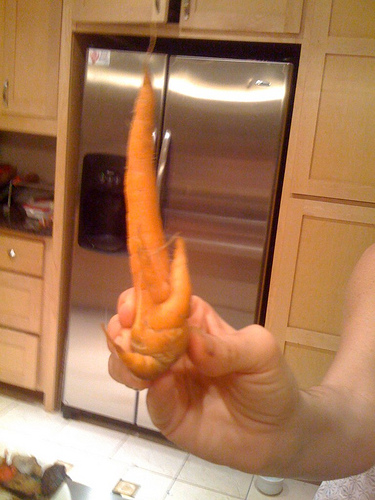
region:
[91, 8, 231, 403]
person holding carrot up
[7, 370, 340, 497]
white tile on floor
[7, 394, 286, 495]
dark grout on floor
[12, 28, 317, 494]
stainless steel fridge in back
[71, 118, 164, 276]
black water dispenser of fridge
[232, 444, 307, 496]
white dish on floor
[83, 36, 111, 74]
white tag on fridqe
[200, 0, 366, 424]
light brown side cabinets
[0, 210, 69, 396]
light brown kitchen drawer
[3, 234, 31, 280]
silver knob on draw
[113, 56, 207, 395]
An odd shaped carrot.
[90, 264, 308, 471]
Hand holding a carrot.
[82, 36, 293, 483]
Large stainless steel refrigerator.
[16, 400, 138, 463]
Tile floor in a kitchen.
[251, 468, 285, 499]
Bowl on the floor.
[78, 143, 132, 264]
Ice maker on a refrigerator.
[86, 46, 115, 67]
Magnet on the refrigerator.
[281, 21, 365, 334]
Several wooden cabinets in the kitchen.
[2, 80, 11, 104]
The handle of a wooden cabinet.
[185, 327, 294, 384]
A person's crooked thumb.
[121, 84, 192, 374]
a nasty looking orange carrot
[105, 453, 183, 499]
a tile kitchen floor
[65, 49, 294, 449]
a silver stainless steel fridge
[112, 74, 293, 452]
a woman holding an orange carrot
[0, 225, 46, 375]
a brown wooden cabinet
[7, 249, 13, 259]
a metal knob on a cabinet door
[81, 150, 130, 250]
a black water dispensor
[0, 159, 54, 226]
a granite kitchen countertop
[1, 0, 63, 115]
a wooden cabinet with metal handle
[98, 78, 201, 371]
a strange orange carrot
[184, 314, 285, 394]
a thumb of a hand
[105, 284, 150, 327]
the index finger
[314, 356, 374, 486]
the elbow is bend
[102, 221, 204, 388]
carrots has bifurcations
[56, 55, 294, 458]
a refrigerator on back a carrot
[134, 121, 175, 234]
handles of a refrigerator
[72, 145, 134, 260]
water dispenser of refrigerator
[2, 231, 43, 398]
cabinets below a counter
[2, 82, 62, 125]
cabinets on top a counter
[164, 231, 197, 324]
a small carrot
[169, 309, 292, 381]
the thumb of a person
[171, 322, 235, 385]
the fingernail of a person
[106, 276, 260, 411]
the hand of a person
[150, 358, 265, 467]
the palm of a person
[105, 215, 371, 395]
the arm of a person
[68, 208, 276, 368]
a refrigerator in a kitchen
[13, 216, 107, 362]
a cabinet in a kitchen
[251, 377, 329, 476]
the wrist of a person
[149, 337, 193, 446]
the pinky of a person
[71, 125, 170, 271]
a ice maker on a refrigerator